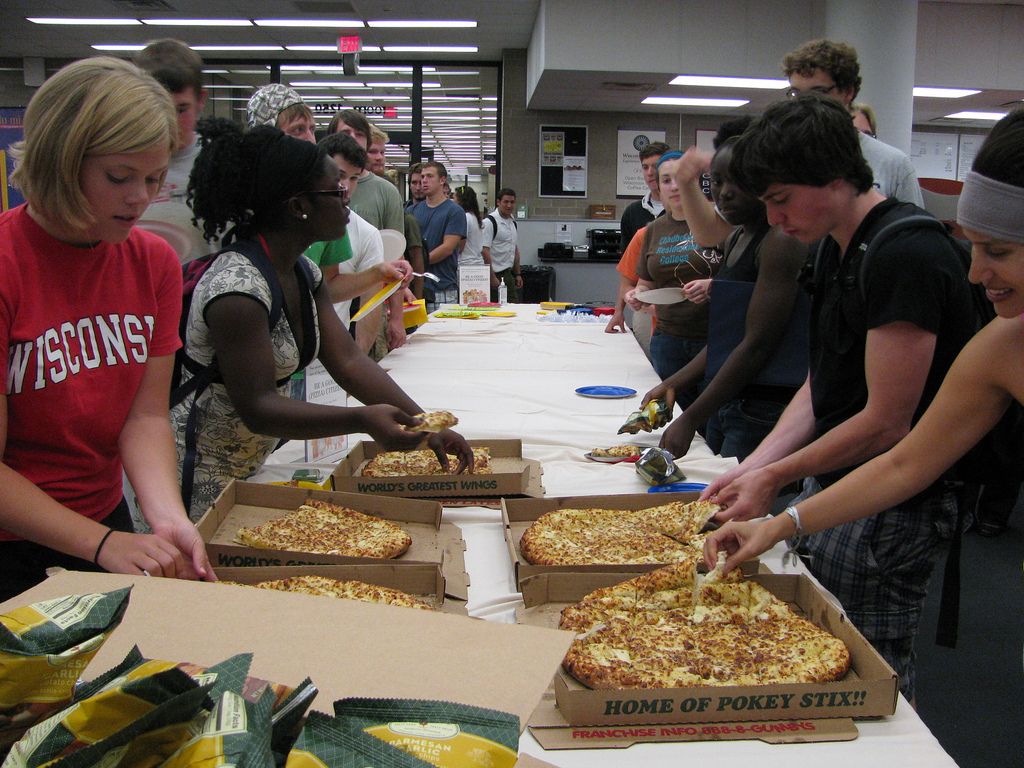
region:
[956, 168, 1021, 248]
Grey headband on a woman's head.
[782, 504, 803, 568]
Silver bracelet on a girl with a grey headbands right wrist.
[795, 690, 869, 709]
Green word STIX!!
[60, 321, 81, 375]
White C in WISCONSIN.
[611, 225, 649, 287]
Right orange t-shirt sleeve.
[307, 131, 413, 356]
Black haired man in a green t-shirt.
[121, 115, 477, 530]
Black woman with dread locks in a white and black dress.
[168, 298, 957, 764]
A long white table.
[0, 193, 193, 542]
Girl is wearing a shirt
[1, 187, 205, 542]
Girl is wearing a red shirt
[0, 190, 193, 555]
Girl is wearing a t-shirt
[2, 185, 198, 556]
Girl is wearing a red t-shirt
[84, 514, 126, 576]
Girl is wearing a bracelet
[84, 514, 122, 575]
Girl is wearing a black bracelet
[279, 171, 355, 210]
Girl is wearing glasses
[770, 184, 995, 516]
Boy is wearing a shirt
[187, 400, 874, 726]
Pizzas are on a table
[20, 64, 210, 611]
woman wearing red shirt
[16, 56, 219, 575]
woman grabbing a slice of pizza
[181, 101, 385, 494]
woman with hair in a pony tail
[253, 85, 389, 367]
boy wearing green shirt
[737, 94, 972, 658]
boy wearing a black shirt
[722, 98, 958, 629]
boy grabbing a slice of pizza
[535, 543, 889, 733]
cheese pizza in a box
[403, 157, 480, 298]
man wearing a blue shirt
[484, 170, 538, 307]
boy wearing a white shirt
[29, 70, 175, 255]
Girl has blonde hair.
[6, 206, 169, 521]
Girl is wearing red t-shirt.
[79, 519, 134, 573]
Black band around girl's wrist.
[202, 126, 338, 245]
Girl has black hair.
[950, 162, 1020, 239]
Woman is wearing gray head band.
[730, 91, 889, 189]
Man has dark hair.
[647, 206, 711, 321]
Person wearing brown and blue shirt.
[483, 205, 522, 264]
Person wearing white shirt.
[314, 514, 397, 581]
pizza in a box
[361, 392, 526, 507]
pizza in a box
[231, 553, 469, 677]
pizza in a box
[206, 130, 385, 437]
a person standing at a table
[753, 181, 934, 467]
a person standing next to table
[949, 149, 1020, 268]
a person standing next to table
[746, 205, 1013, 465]
a person standing next to table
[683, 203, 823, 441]
a person standing next to table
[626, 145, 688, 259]
a person standing next to table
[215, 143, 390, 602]
a person standing next to table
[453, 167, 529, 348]
a person standing next to table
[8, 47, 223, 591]
girl wearing a red shirt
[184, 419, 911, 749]
pizzas on a table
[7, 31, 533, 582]
a line of people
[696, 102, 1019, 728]
a lady grabbing some pizza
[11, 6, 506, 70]
lights on the ceiling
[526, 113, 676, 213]
pictures on a wall